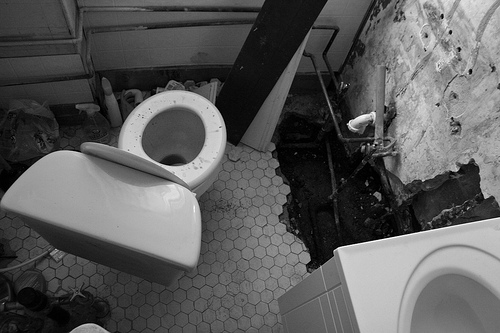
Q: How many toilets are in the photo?
A: One.